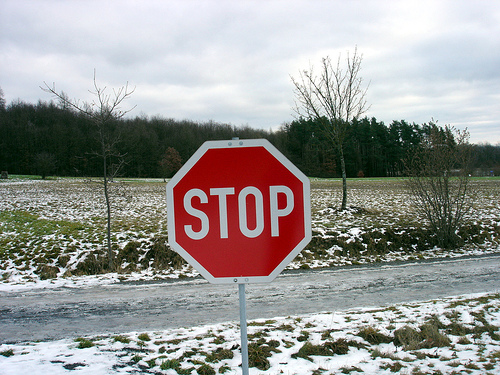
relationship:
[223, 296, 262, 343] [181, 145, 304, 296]
pole on sign